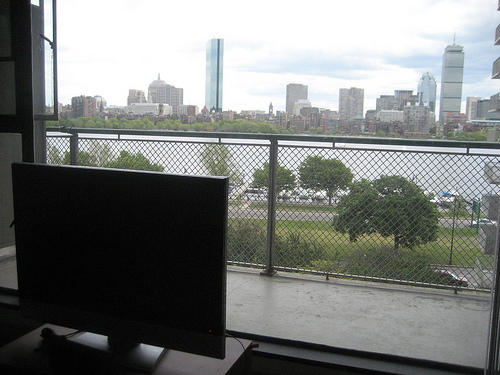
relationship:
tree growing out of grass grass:
[297, 157, 434, 271] [421, 225, 469, 265]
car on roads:
[468, 212, 499, 234] [228, 189, 333, 226]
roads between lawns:
[228, 189, 333, 226] [296, 216, 366, 251]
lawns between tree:
[296, 216, 366, 251] [327, 174, 439, 254]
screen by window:
[6, 157, 243, 368] [40, 3, 498, 353]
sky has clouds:
[28, 5, 498, 120] [328, 24, 398, 83]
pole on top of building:
[448, 27, 463, 52] [441, 27, 468, 110]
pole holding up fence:
[263, 137, 278, 287] [34, 120, 498, 304]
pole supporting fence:
[263, 137, 278, 287] [34, 120, 498, 304]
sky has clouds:
[28, 5, 498, 120] [30, 5, 498, 119]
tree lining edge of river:
[63, 96, 488, 178] [72, 95, 495, 245]